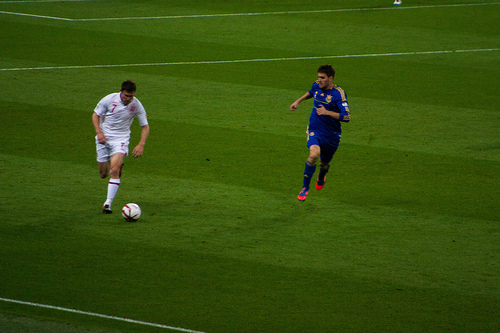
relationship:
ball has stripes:
[121, 202, 141, 223] [122, 206, 136, 221]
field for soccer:
[1, 2, 499, 332] [22, 17, 443, 308]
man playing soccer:
[290, 64, 351, 202] [22, 17, 443, 308]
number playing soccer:
[111, 104, 117, 113] [22, 17, 443, 308]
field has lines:
[1, 2, 499, 332] [0, 2, 499, 73]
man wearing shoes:
[91, 79, 150, 212] [101, 202, 112, 214]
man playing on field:
[91, 79, 150, 212] [1, 2, 499, 332]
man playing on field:
[290, 65, 352, 201] [1, 2, 499, 332]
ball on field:
[121, 202, 141, 223] [0, 0, 499, 333]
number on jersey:
[109, 103, 119, 113] [93, 92, 149, 141]